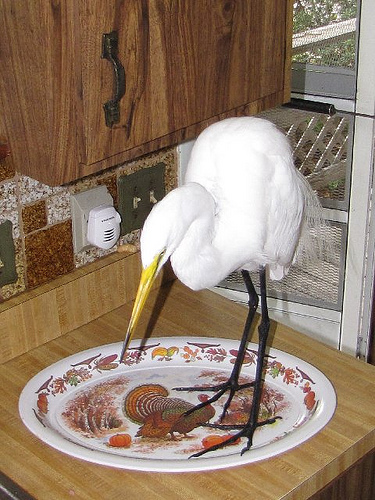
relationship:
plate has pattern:
[18, 336, 336, 471] [62, 372, 279, 445]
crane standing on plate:
[121, 118, 318, 459] [18, 336, 336, 471]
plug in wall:
[70, 194, 122, 249] [1, 130, 184, 361]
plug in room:
[70, 194, 122, 249] [0, 1, 374, 499]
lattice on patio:
[277, 116, 357, 182] [278, 0, 373, 359]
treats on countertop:
[48, 360, 325, 457] [2, 284, 373, 498]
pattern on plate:
[62, 372, 279, 445] [18, 336, 336, 471]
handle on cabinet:
[102, 33, 126, 127] [0, 1, 292, 185]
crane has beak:
[121, 118, 318, 459] [116, 263, 162, 365]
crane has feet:
[121, 118, 318, 459] [171, 379, 280, 459]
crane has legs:
[121, 118, 318, 459] [230, 270, 272, 415]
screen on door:
[226, 0, 349, 307] [188, 12, 371, 357]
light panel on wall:
[115, 165, 166, 233] [1, 130, 184, 361]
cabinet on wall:
[0, 1, 292, 185] [1, 130, 184, 361]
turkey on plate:
[123, 384, 215, 445] [18, 336, 336, 471]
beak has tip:
[116, 263, 162, 365] [120, 330, 137, 364]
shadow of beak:
[139, 274, 181, 361] [116, 263, 162, 365]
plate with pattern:
[18, 336, 336, 471] [62, 372, 279, 445]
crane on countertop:
[121, 118, 318, 459] [2, 284, 373, 498]